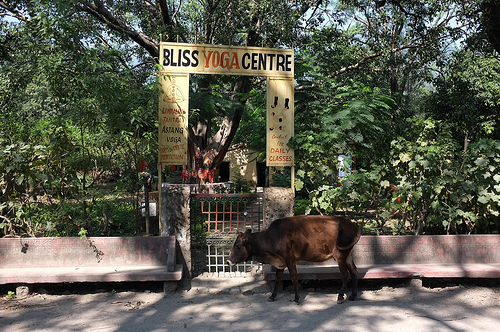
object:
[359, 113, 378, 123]
leaves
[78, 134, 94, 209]
wood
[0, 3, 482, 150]
background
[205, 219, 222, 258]
metal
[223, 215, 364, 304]
cow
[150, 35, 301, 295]
center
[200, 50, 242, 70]
yoga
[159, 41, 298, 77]
bliss yoga center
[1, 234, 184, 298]
benche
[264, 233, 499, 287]
bench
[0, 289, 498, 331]
ground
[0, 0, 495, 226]
trees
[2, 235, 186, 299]
benches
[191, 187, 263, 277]
fence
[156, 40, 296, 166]
sign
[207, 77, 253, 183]
trunk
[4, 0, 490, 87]
sky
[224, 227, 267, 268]
side view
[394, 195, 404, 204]
red ojects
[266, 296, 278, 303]
hooves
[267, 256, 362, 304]
four legs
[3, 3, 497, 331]
day time